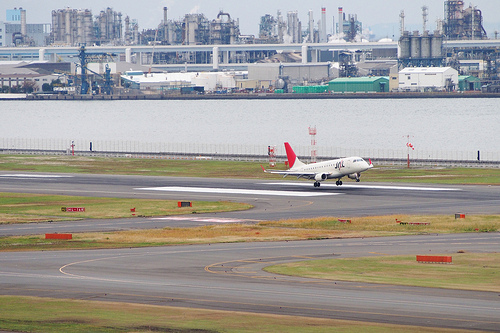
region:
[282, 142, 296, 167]
the red tail fin of a plane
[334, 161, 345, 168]
letters on the side of the plane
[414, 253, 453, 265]
red marker on the ground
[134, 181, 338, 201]
white rectangle on the tarmac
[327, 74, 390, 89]
a green storage building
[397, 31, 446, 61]
a group of 4 large batteries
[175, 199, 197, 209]
a black and red runway marker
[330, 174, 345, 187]
the landing gear of a plane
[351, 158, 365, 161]
the front windows of the airplane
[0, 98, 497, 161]
a river next to the airport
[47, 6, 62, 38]
a tall building outside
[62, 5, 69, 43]
a tall building outside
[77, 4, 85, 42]
a tall building outside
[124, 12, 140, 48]
a tall building outside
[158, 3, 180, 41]
a tall building outside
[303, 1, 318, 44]
a tall building outside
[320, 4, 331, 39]
a tall building outside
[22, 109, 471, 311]
A plane is at an airport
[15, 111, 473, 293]
A plane is going down the runway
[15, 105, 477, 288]
The plane is obeying the law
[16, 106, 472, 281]
The plane is operating in daytime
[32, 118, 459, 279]
The plane has powerful jet engines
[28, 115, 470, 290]
The plane is close to a city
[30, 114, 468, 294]
The plane is taking people home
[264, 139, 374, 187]
Airplane driving on a runway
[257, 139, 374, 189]
White and red airplane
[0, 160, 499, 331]
Runways at an airport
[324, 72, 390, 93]
Metal green barn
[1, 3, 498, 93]
Large industrial complex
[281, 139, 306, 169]
Red and white fin on a plane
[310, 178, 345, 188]
Four black airplane landing wheels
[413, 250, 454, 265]
Orange rectangle in the grass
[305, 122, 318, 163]
Orange and white antenna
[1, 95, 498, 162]
Gray river between and airport and buildings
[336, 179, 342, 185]
wheels on the plane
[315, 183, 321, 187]
wheels on the plane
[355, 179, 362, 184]
wheels on the plane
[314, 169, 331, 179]
engine on the plane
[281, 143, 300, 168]
tail fin on the plane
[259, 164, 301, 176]
wing on the plane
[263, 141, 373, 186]
plane on the runway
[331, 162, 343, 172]
logo on the plane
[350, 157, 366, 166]
windshield on the plane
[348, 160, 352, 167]
door on the plane